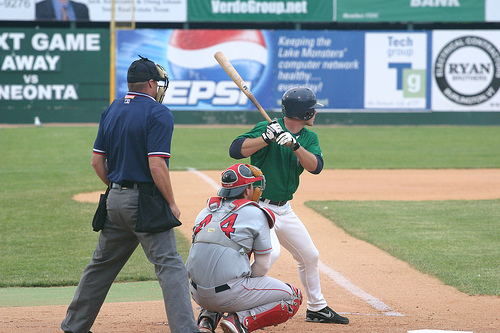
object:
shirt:
[185, 199, 272, 287]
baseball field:
[0, 125, 500, 333]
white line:
[187, 162, 395, 313]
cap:
[217, 163, 264, 196]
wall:
[0, 19, 498, 124]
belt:
[188, 275, 247, 293]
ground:
[398, 125, 428, 185]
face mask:
[136, 54, 170, 104]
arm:
[145, 105, 180, 218]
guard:
[59, 56, 206, 333]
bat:
[213, 51, 291, 147]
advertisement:
[116, 27, 369, 112]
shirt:
[91, 91, 174, 182]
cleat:
[305, 305, 350, 325]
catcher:
[185, 162, 304, 333]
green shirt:
[228, 120, 323, 202]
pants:
[246, 200, 327, 312]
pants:
[61, 188, 200, 332]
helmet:
[279, 87, 324, 121]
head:
[280, 88, 324, 126]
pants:
[188, 274, 301, 332]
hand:
[276, 132, 302, 151]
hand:
[261, 120, 283, 145]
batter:
[228, 87, 351, 325]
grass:
[372, 199, 483, 228]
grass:
[446, 239, 497, 295]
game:
[10, 12, 485, 285]